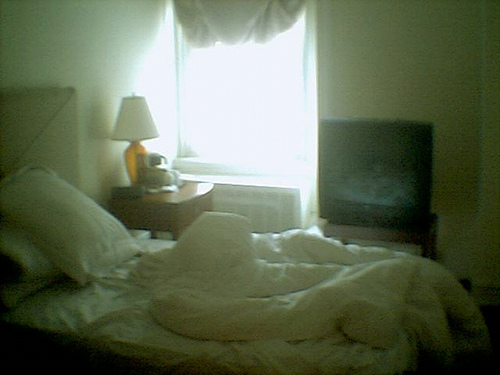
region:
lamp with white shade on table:
[105, 90, 163, 189]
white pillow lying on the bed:
[0, 147, 157, 287]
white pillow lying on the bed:
[0, 217, 57, 289]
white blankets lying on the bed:
[128, 210, 496, 374]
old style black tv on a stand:
[310, 108, 444, 233]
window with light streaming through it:
[172, 2, 322, 173]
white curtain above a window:
[152, 0, 321, 52]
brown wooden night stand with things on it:
[103, 173, 220, 243]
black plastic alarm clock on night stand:
[107, 181, 146, 198]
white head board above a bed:
[0, 80, 91, 187]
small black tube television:
[313, 110, 439, 234]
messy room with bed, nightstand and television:
[2, 2, 496, 368]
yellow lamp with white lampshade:
[109, 89, 160, 194]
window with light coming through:
[164, 4, 319, 181]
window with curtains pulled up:
[163, 0, 318, 185]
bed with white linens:
[2, 89, 483, 374]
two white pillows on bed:
[4, 161, 144, 300]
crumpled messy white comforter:
[131, 201, 488, 371]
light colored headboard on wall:
[4, 84, 85, 281]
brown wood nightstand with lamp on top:
[108, 89, 217, 239]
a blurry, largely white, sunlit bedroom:
[2, 1, 499, 373]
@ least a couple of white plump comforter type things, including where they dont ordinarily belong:
[0, 1, 499, 373]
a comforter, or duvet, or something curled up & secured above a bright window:
[171, 1, 312, 78]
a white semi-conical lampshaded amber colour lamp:
[104, 84, 169, 191]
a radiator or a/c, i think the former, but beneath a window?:
[202, 172, 314, 244]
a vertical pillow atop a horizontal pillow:
[2, 155, 154, 306]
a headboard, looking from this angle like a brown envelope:
[0, 76, 90, 222]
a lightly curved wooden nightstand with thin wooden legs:
[104, 176, 223, 242]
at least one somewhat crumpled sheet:
[17, 217, 423, 373]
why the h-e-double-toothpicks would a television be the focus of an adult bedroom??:
[307, 106, 449, 248]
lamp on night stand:
[100, 85, 173, 195]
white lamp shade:
[102, 89, 164, 144]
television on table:
[298, 103, 438, 233]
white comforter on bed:
[141, 210, 492, 370]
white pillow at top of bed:
[2, 148, 148, 288]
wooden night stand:
[100, 153, 220, 245]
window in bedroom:
[168, 5, 322, 182]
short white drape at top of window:
[168, 0, 310, 57]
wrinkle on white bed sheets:
[55, 294, 157, 344]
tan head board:
[3, 76, 90, 203]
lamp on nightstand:
[96, 87, 176, 194]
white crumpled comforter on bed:
[140, 213, 492, 363]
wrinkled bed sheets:
[46, 290, 143, 348]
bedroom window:
[168, 8, 312, 190]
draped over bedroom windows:
[167, 2, 317, 65]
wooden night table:
[103, 163, 219, 238]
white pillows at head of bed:
[3, 156, 155, 295]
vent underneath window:
[213, 180, 309, 239]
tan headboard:
[3, 79, 95, 203]